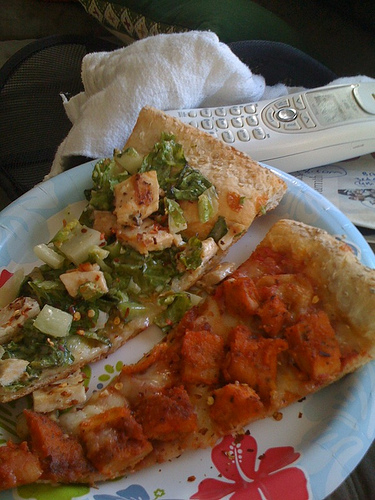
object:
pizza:
[0, 218, 375, 490]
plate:
[0, 155, 374, 498]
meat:
[207, 382, 265, 432]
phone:
[161, 76, 375, 173]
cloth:
[43, 28, 288, 182]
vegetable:
[112, 249, 145, 274]